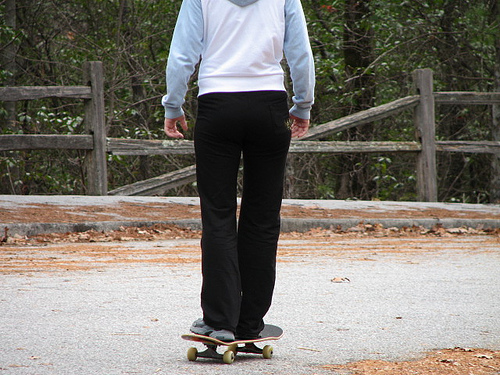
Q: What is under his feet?
A: A skateboard.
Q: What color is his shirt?
A: White.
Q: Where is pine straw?
A: Scattered in the street.